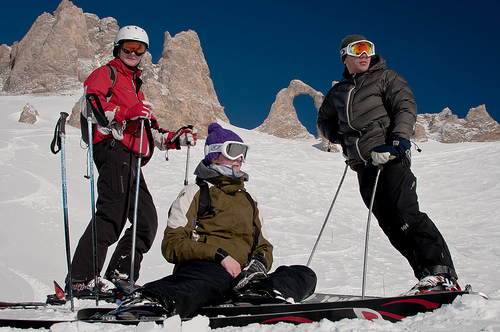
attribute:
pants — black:
[353, 161, 456, 278]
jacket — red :
[83, 57, 153, 154]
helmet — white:
[113, 24, 149, 46]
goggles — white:
[202, 140, 252, 157]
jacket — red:
[73, 61, 188, 151]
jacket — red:
[38, 59, 235, 179]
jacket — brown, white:
[318, 50, 412, 168]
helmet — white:
[109, 20, 152, 45]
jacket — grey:
[315, 55, 418, 165]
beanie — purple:
[202, 120, 243, 164]